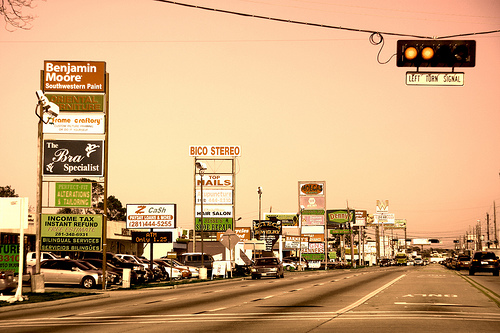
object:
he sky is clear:
[0, 0, 499, 245]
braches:
[6, 0, 22, 19]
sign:
[43, 60, 104, 93]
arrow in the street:
[399, 293, 415, 298]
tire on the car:
[83, 275, 94, 287]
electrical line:
[157, 0, 430, 39]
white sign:
[369, 213, 395, 226]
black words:
[405, 74, 421, 84]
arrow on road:
[451, 293, 457, 298]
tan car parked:
[33, 257, 112, 288]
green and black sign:
[406, 72, 465, 87]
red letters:
[190, 146, 196, 155]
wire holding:
[436, 30, 500, 41]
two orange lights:
[403, 47, 433, 60]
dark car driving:
[467, 250, 500, 276]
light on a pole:
[401, 47, 419, 61]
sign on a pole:
[232, 157, 237, 226]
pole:
[191, 160, 196, 253]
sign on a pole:
[44, 110, 106, 135]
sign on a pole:
[40, 139, 103, 174]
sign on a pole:
[188, 145, 239, 155]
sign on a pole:
[323, 180, 329, 270]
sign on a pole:
[300, 182, 327, 197]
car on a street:
[250, 255, 285, 278]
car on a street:
[176, 253, 214, 269]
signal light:
[419, 47, 433, 61]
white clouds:
[0, 0, 499, 247]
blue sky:
[0, 0, 500, 233]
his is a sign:
[326, 209, 358, 222]